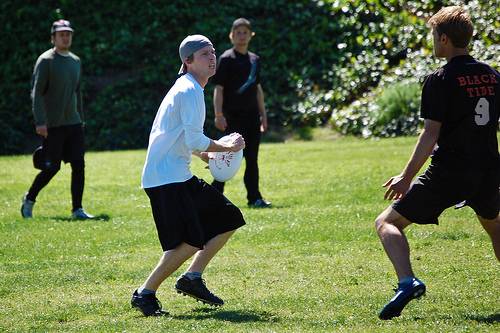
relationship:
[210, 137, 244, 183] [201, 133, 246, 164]
ball in hands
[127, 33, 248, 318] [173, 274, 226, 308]
man has sneaker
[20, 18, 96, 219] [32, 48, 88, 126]
man wearing shirt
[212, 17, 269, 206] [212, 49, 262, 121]
spectator wearing shirt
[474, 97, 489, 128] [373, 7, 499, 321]
number on opponent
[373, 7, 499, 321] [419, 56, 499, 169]
opponent wearing shirt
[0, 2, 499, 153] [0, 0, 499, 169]
trees in background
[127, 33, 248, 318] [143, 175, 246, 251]
man wearing shorts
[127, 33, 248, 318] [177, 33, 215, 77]
man has hat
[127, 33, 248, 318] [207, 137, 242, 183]
man holding frisbee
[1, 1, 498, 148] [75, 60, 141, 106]
vegetation covering rocks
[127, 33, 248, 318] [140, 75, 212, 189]
man wearing shirt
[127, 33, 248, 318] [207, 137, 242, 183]
man has frisbee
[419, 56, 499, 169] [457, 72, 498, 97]
shirt has lettering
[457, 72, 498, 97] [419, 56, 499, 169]
lettering on shirt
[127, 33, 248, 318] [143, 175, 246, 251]
man has shorts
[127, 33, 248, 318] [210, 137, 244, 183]
man holding ball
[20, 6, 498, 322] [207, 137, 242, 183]
men playing with frisbee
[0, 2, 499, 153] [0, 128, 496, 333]
trees behind field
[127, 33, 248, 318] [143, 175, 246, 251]
man in shorts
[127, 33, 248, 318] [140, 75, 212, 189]
man in shirt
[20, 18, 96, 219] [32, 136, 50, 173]
man holding cap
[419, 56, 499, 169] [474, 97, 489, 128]
shirt has number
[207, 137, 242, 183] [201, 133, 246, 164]
frisbee in hands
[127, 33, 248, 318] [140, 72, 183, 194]
man has backside